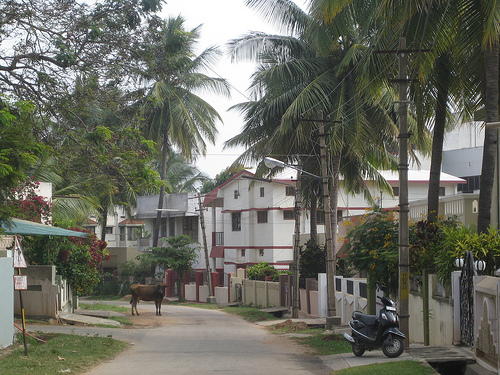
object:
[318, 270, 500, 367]
fence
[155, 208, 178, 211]
street light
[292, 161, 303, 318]
pole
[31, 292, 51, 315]
wall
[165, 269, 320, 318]
fence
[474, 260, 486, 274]
light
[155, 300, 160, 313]
legs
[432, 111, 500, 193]
building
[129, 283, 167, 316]
cow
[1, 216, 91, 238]
awning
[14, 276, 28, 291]
sign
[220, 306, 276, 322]
grass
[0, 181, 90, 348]
house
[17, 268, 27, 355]
pole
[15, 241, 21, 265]
person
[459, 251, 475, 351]
gate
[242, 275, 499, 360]
wall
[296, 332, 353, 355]
grass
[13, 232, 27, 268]
sign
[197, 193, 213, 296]
pole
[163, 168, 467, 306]
building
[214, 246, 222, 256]
red accents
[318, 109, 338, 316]
pole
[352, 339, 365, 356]
wheels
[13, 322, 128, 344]
street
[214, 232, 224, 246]
railing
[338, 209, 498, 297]
plants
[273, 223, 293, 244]
wall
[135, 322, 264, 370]
drive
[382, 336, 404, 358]
wheel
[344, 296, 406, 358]
bike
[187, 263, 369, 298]
yard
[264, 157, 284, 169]
light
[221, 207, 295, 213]
trim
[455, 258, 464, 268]
lamps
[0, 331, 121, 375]
grass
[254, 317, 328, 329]
drive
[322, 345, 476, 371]
pad